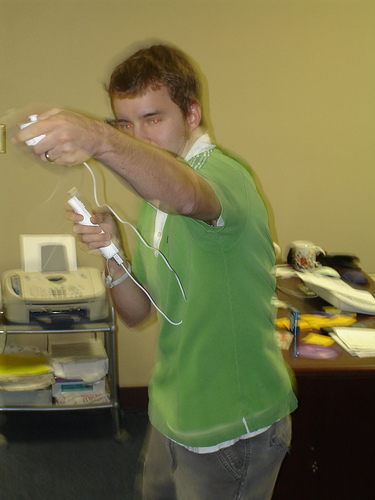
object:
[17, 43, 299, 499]
male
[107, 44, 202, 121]
hair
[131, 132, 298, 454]
shirt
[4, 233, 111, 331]
fax machine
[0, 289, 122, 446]
cart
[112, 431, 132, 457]
wheels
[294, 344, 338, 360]
cd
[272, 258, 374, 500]
desk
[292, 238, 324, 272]
coffee mug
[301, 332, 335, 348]
post it note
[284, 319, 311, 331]
post it notes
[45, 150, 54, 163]
wedding band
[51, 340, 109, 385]
rea of paper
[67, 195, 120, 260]
wiimote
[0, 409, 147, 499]
floor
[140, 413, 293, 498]
pants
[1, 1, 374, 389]
wall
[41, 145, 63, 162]
finger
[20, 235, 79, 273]
paper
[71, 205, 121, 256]
hand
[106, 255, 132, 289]
wrist strap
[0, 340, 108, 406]
reams of papers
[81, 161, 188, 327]
chord